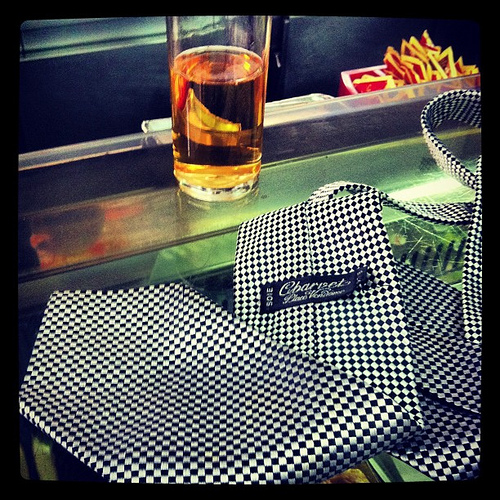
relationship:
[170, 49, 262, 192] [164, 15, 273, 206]
beverage in clear glass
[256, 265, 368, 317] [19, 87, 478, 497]
tag on back of cloth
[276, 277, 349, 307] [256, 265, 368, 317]
lettering on tag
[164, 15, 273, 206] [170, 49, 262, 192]
clear glass of beverage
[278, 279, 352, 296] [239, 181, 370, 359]
lettering on tie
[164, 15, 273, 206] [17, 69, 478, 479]
clear glass on counter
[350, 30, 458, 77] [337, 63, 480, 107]
packets in box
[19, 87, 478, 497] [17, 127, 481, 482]
cloth on glass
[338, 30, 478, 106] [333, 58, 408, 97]
packets in container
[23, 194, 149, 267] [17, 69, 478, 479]
reflection in counter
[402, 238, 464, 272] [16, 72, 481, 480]
black writing on table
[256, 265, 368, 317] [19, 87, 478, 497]
tag on cloth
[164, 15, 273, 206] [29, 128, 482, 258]
clear glass sitting on counter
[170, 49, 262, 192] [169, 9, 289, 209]
beverage in glass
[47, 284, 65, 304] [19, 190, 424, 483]
tip of tie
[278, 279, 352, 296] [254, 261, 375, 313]
lettering on tag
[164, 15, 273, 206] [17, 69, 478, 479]
clear glass in counter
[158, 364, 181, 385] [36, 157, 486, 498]
design on cloth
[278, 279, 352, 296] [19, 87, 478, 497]
lettering of cloth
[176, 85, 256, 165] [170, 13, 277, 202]
shadow in glass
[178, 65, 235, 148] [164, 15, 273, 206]
reflection seen in clear glass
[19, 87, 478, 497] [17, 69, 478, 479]
cloth lying on top of counter